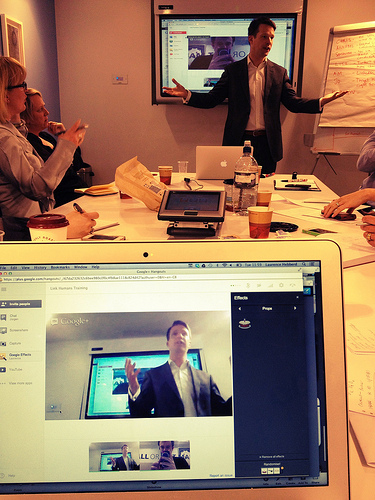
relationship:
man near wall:
[173, 6, 324, 167] [52, 4, 374, 183]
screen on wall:
[158, 14, 300, 104] [52, 4, 374, 183]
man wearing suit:
[173, 6, 324, 167] [199, 60, 303, 158]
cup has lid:
[26, 210, 72, 241] [23, 212, 70, 229]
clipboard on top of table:
[272, 172, 322, 195] [0, 167, 368, 498]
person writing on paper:
[0, 191, 102, 247] [88, 215, 127, 241]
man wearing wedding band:
[173, 6, 324, 167] [180, 55, 321, 178]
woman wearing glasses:
[0, 52, 87, 220] [0, 81, 32, 96]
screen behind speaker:
[161, 12, 296, 95] [159, 14, 347, 174]